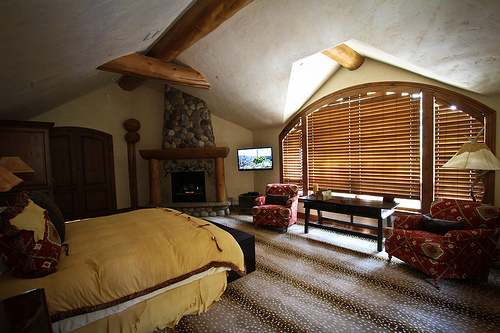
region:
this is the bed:
[77, 201, 209, 323]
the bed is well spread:
[87, 195, 197, 329]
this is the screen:
[237, 145, 275, 171]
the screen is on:
[236, 145, 275, 172]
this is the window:
[327, 98, 422, 185]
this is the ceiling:
[242, 15, 299, 74]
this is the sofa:
[250, 184, 297, 224]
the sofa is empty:
[252, 179, 297, 226]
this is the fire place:
[171, 168, 208, 202]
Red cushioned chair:
[250, 178, 298, 235]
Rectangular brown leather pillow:
[418, 209, 465, 236]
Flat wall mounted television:
[235, 144, 274, 172]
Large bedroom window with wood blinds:
[277, 80, 493, 216]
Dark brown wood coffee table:
[298, 189, 398, 251]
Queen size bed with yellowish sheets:
[0, 193, 246, 330]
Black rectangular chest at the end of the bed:
[195, 213, 257, 283]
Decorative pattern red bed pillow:
[1, 190, 63, 280]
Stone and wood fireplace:
[140, 83, 231, 218]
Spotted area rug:
[151, 215, 498, 331]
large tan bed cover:
[71, 220, 244, 332]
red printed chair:
[371, 202, 485, 274]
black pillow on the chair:
[421, 217, 451, 237]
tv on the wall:
[222, 138, 279, 183]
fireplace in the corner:
[154, 96, 229, 211]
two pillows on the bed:
[0, 162, 87, 274]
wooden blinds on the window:
[278, 95, 445, 191]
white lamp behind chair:
[451, 136, 497, 200]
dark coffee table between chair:
[305, 192, 384, 252]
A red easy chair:
[249, 180, 300, 232]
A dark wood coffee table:
[299, 191, 400, 253]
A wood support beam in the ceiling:
[317, 41, 364, 71]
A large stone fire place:
[155, 83, 230, 216]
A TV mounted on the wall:
[236, 146, 273, 173]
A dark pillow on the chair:
[416, 210, 459, 235]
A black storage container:
[196, 218, 259, 283]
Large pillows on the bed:
[0, 187, 71, 277]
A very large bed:
[0, 201, 245, 332]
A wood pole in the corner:
[121, 115, 145, 208]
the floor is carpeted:
[277, 249, 410, 324]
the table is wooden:
[292, 174, 391, 251]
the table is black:
[303, 187, 390, 254]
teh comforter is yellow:
[55, 208, 246, 277]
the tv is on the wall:
[235, 145, 280, 172]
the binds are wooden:
[313, 99, 417, 199]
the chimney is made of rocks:
[156, 96, 215, 140]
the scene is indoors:
[2, 57, 497, 332]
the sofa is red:
[249, 177, 301, 229]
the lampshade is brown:
[443, 137, 495, 177]